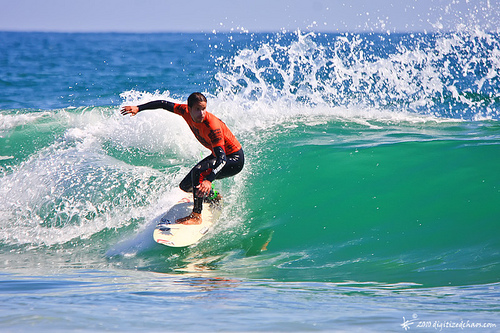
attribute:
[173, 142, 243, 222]
pants — black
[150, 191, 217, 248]
surfboard — white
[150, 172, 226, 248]
surfboard — white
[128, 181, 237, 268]
surfboard — white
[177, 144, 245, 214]
pants — black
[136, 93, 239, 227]
person — surfing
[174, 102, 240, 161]
shirt — red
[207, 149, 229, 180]
sleeve — black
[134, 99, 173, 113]
sleeve — black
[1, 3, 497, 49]
sky — pale, blue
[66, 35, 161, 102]
water — blue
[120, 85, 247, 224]
person — black, orange, wearing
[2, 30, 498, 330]
water — green, blue, beautiful, gorgeous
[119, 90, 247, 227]
surfer — barefoot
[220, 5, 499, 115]
foam — white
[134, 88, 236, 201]
wetsuit — red, black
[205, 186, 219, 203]
strap — green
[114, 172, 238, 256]
surfboard — white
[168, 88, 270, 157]
shirt — red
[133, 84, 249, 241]
person — wearing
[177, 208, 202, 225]
foot — bare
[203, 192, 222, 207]
foot — bare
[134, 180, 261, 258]
surfboard — white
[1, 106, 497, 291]
water — turquoise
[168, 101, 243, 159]
shirt — red